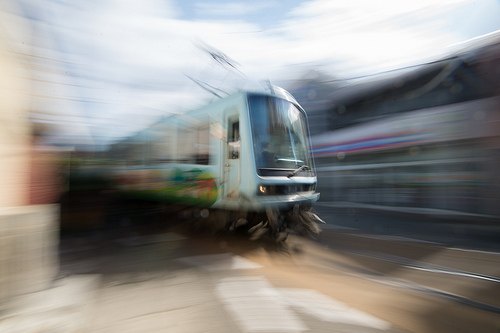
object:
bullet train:
[310, 27, 500, 235]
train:
[59, 84, 329, 246]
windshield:
[246, 92, 317, 177]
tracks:
[435, 288, 473, 304]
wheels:
[194, 206, 213, 222]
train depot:
[0, 0, 77, 304]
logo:
[73, 167, 219, 209]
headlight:
[259, 185, 267, 194]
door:
[221, 112, 241, 201]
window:
[225, 113, 241, 159]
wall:
[0, 202, 62, 303]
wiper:
[286, 164, 310, 178]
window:
[176, 114, 210, 165]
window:
[144, 127, 172, 165]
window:
[124, 143, 145, 166]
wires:
[187, 76, 195, 81]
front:
[239, 84, 322, 213]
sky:
[0, 1, 499, 76]